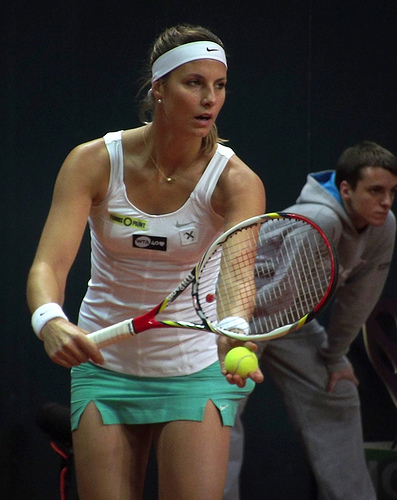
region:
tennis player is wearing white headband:
[110, 25, 244, 78]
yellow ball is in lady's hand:
[216, 341, 265, 387]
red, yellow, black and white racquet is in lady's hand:
[58, 207, 350, 344]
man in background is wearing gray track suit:
[253, 139, 395, 498]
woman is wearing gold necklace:
[136, 123, 203, 183]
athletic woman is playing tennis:
[29, 19, 291, 498]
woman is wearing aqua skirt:
[61, 349, 258, 432]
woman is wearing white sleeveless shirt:
[75, 129, 228, 373]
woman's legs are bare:
[69, 400, 224, 494]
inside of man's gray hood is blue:
[299, 168, 355, 223]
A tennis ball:
[214, 329, 304, 431]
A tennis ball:
[174, 266, 271, 408]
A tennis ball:
[193, 279, 302, 448]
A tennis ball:
[214, 318, 269, 458]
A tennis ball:
[228, 331, 292, 498]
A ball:
[220, 302, 306, 469]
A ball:
[235, 360, 265, 446]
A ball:
[191, 265, 325, 490]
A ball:
[231, 324, 282, 444]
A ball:
[193, 323, 269, 416]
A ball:
[212, 328, 278, 491]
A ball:
[173, 324, 255, 457]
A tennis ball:
[214, 342, 275, 413]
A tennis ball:
[196, 306, 245, 375]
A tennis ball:
[219, 332, 287, 377]